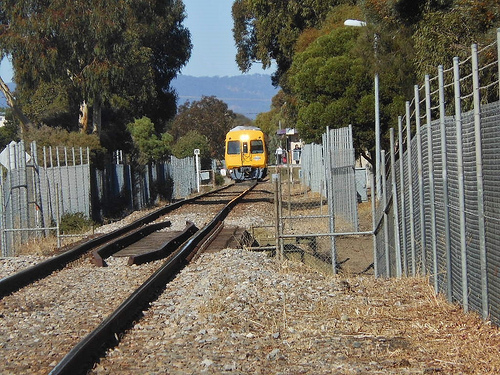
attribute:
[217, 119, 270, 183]
bus — yellow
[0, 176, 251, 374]
tracks — train tracks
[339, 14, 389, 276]
light — grey, light pole, on right side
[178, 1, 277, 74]
sky — blue, clear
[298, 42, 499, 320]
fence — silver, metal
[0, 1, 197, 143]
trees — green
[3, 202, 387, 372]
rocks — grey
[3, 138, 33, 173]
diamond — to the back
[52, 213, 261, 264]
bridge — wooden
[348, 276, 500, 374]
grass — dried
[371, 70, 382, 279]
pole — white